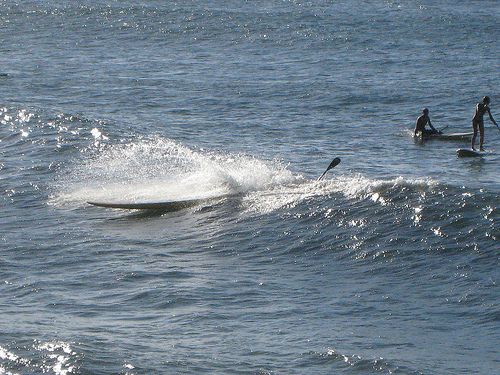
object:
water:
[82, 29, 197, 134]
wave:
[125, 157, 368, 224]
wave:
[150, 117, 408, 232]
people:
[416, 92, 498, 156]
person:
[469, 92, 498, 154]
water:
[340, 159, 497, 279]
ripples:
[28, 212, 404, 359]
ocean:
[0, 3, 499, 372]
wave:
[34, 122, 499, 239]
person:
[412, 105, 442, 135]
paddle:
[316, 155, 342, 182]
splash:
[57, 121, 264, 179]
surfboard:
[85, 187, 256, 208]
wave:
[25, 328, 128, 373]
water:
[1, 0, 496, 373]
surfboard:
[455, 145, 484, 160]